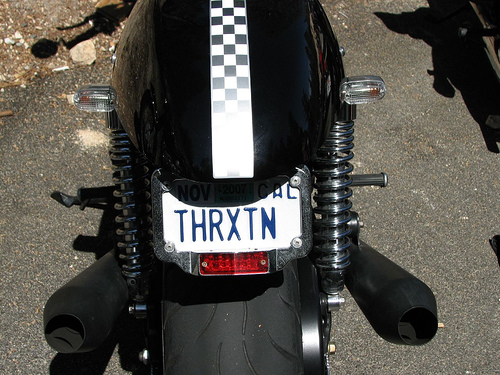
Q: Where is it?
A: This is at the pavement.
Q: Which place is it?
A: It is a pavement.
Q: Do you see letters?
A: Yes, there are letters.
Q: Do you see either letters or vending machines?
A: Yes, there are letters.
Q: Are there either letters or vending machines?
A: Yes, there are letters.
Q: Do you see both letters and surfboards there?
A: No, there are letters but no surfboards.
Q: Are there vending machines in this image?
A: No, there are no vending machines.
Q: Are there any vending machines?
A: No, there are no vending machines.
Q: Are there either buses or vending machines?
A: No, there are no vending machines or buses.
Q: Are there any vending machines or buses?
A: No, there are no vending machines or buses.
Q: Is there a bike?
A: Yes, there is a bike.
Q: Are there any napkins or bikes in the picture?
A: Yes, there is a bike.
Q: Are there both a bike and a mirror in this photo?
A: No, there is a bike but no mirrors.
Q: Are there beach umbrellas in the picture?
A: No, there are no beach umbrellas.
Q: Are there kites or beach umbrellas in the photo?
A: No, there are no beach umbrellas or kites.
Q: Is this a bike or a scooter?
A: This is a bike.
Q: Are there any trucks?
A: No, there are no trucks.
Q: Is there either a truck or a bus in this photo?
A: No, there are no trucks or buses.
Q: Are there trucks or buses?
A: No, there are no trucks or buses.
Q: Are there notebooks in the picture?
A: No, there are no notebooks.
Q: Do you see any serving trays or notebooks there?
A: No, there are no notebooks or serving trays.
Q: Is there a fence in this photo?
A: No, there are no fences.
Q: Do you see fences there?
A: No, there are no fences.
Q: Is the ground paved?
A: Yes, the ground is paved.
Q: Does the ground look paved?
A: Yes, the ground is paved.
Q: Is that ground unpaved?
A: No, the ground is paved.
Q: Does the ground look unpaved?
A: No, the ground is paved.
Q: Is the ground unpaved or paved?
A: The ground is paved.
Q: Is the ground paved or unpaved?
A: The ground is paved.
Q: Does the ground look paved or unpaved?
A: The ground is paved.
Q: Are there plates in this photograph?
A: Yes, there is a plate.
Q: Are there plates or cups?
A: Yes, there is a plate.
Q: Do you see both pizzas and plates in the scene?
A: No, there is a plate but no pizzas.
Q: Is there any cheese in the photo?
A: No, there is no cheese.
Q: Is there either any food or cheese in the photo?
A: No, there are no cheese or food.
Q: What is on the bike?
A: The plate is on the bike.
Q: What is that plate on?
A: The plate is on the bike.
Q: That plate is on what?
A: The plate is on the bike.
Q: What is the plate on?
A: The plate is on the bike.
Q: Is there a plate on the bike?
A: Yes, there is a plate on the bike.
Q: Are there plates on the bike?
A: Yes, there is a plate on the bike.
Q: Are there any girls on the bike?
A: No, there is a plate on the bike.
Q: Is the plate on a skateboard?
A: No, the plate is on the bike.